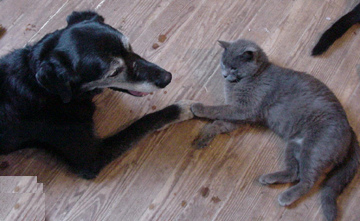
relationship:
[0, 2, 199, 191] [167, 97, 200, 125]
dog has paw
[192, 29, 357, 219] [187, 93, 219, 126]
cat has paw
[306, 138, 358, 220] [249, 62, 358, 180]
tail on body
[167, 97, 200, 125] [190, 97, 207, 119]
paw touch paw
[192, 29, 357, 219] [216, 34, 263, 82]
cat has head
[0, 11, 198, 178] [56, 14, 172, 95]
dog has head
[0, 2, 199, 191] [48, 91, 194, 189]
dog has leg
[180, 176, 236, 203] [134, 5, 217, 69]
spots on floor